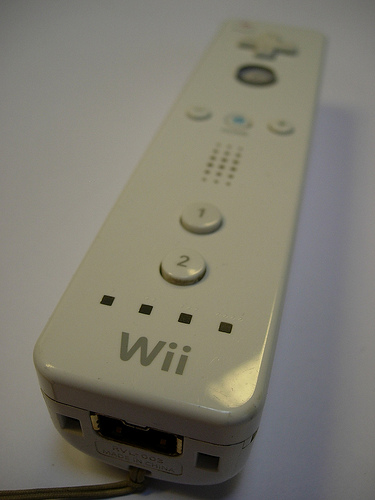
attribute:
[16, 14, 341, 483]
wii remote — white, nintendo, plastic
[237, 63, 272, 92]
home button — small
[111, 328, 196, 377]
wii logo — grey, saying wii, gray, brand name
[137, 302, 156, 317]
power light — dark, little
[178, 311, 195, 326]
power light — off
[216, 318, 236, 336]
power light — off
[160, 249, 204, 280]
button — white, small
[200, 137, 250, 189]
speaker — small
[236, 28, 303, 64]
directional button — white, small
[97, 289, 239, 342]
row of lights — small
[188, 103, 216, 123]
minus button — round, small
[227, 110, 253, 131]
button — blue, white